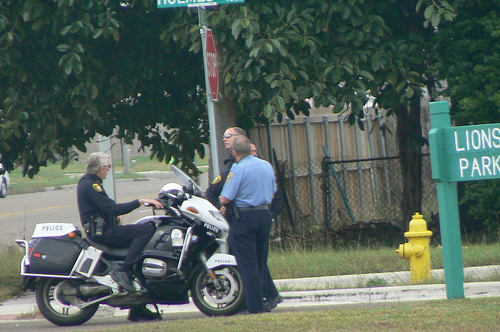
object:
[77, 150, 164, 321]
cop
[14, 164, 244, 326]
bike